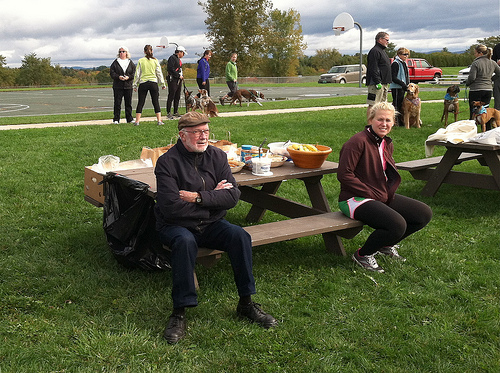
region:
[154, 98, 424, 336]
two people sitting at picnic table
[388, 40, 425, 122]
woman wearing blue vest with dog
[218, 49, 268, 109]
person wearing green shirt with dog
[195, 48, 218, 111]
man wearing blue shirt walking dog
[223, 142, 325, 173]
food on the picnic table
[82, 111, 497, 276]
two picnic tables on the grass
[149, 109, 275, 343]
older gentleman sitting on bench of picnic table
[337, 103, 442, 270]
woman wearing brown jacket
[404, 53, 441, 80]
red truck in the parking lot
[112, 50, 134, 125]
woman wearing black jacket and black pants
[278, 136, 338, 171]
Banana's are in the bowl.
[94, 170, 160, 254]
Garbage bag taped to table.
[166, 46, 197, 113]
Man with dog on a leash.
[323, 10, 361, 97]
A basketball court in the background.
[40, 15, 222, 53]
Gray clouds above.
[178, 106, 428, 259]
Man and woman sitting on bench.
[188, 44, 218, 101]
Woman is wearing a purple jacket.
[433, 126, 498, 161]
White tablecloth sitting on table.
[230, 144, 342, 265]
Picnic bench with many foods on it.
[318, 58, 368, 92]
A gold car sitting behind basketball net.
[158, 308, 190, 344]
the man's right foot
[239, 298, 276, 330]
the man's left foot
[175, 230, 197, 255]
the man's right knee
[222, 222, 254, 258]
the man's left knee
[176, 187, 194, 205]
the man's left hand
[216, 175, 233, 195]
the man's right hand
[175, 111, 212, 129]
brown hat on the man's head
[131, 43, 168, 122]
woman in a yellow shirt standing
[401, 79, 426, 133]
golden retriever sitting next to people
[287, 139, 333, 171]
orange bowl on a picnic table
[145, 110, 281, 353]
old man on a bench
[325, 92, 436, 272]
woman sitting on a bench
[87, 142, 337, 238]
picnic table with food set out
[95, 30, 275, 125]
group of people standing with dogs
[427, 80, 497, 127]
dogs with blue bandanas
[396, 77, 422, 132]
golden retriever standing by owner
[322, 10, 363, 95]
basketball hoop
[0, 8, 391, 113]
basketball court at park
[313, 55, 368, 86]
car in parking lot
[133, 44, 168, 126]
woman in yellow and white jacket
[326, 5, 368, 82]
Basketball goal on grey pole.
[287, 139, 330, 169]
A large orange bowl.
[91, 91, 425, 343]
Two people sitting at picnic table.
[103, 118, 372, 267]
A wood picnic table.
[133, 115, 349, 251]
Food on picnic table.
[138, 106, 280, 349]
Older man sitting at picnic table.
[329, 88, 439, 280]
Woman with blonde hair.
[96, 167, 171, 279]
Black trash bag on end of table.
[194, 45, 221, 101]
Person wearing a blue jacket.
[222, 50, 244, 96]
Person wearing a green jacket.